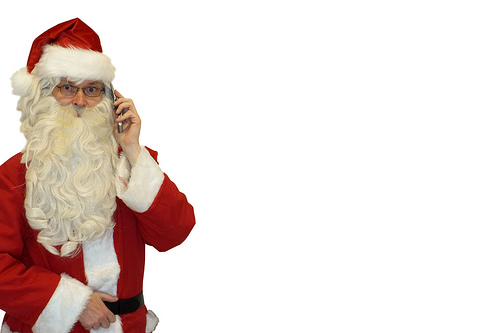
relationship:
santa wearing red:
[3, 15, 196, 323] [5, 15, 195, 332]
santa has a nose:
[3, 15, 196, 323] [71, 86, 86, 108]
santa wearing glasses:
[3, 15, 196, 323] [53, 79, 104, 101]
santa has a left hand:
[3, 15, 196, 323] [110, 87, 141, 156]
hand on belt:
[75, 287, 122, 332] [107, 290, 146, 318]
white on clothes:
[78, 240, 125, 331] [2, 14, 193, 330]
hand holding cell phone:
[110, 87, 141, 156] [111, 89, 124, 132]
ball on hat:
[7, 69, 33, 99] [12, 18, 116, 95]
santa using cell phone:
[3, 15, 196, 323] [111, 89, 124, 132]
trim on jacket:
[78, 240, 125, 331] [0, 146, 196, 331]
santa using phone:
[3, 15, 196, 323] [111, 89, 124, 132]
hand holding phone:
[110, 87, 141, 156] [111, 89, 124, 132]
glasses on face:
[53, 79, 104, 101] [32, 77, 115, 134]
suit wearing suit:
[3, 15, 196, 323] [3, 15, 196, 323]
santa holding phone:
[3, 15, 196, 323] [111, 89, 124, 132]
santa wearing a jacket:
[3, 15, 196, 323] [0, 146, 196, 331]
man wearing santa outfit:
[3, 15, 196, 323] [6, 21, 184, 331]